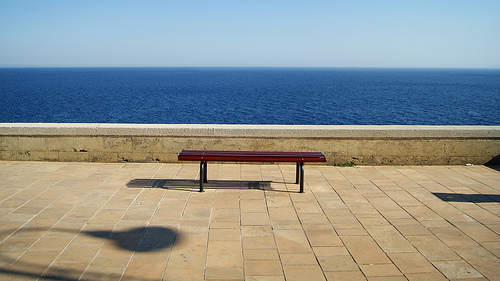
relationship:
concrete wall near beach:
[1, 123, 498, 140] [0, 65, 500, 116]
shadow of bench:
[125, 176, 296, 197] [176, 150, 327, 195]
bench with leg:
[173, 142, 329, 197] [194, 160, 206, 188]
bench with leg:
[173, 142, 329, 197] [203, 161, 208, 184]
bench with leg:
[173, 142, 329, 197] [294, 162, 300, 186]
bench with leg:
[173, 142, 329, 197] [295, 165, 307, 190]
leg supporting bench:
[297, 161, 306, 191] [179, 149, 325, 192]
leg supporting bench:
[198, 164, 205, 190] [179, 149, 325, 192]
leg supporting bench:
[201, 159, 206, 186] [179, 149, 325, 192]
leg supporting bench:
[293, 164, 298, 187] [179, 149, 325, 192]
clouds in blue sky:
[0, 1, 467, 61] [1, 0, 498, 74]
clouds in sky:
[0, 1, 467, 61] [0, 2, 480, 63]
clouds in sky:
[58, 28, 423, 60] [1, 6, 483, 69]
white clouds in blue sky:
[425, 26, 477, 55] [181, 10, 355, 50]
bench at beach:
[173, 142, 329, 197] [0, 65, 471, 152]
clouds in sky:
[0, 6, 455, 59] [6, 6, 491, 93]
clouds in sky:
[117, 25, 359, 62] [0, 2, 480, 63]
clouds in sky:
[323, 27, 438, 60] [0, 2, 480, 63]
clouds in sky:
[0, 1, 467, 61] [138, 12, 251, 47]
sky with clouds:
[88, 8, 459, 68] [0, 1, 467, 61]